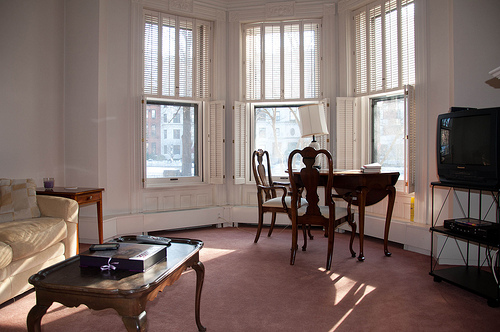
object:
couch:
[0, 177, 80, 279]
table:
[28, 233, 206, 329]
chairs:
[251, 147, 357, 271]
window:
[129, 7, 437, 186]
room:
[6, 2, 497, 297]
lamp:
[298, 103, 330, 173]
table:
[286, 167, 401, 262]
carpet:
[211, 246, 280, 280]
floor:
[217, 273, 430, 331]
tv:
[436, 107, 500, 192]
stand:
[428, 178, 500, 308]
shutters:
[147, 18, 413, 96]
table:
[36, 185, 106, 254]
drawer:
[77, 191, 101, 203]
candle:
[43, 177, 55, 192]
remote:
[136, 234, 172, 245]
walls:
[17, 35, 132, 146]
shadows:
[258, 263, 366, 330]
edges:
[133, 23, 172, 205]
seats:
[261, 195, 354, 220]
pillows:
[0, 173, 42, 223]